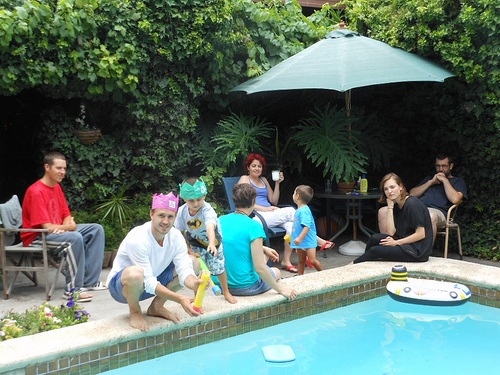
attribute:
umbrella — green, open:
[227, 14, 460, 111]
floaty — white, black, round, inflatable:
[384, 263, 475, 310]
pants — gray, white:
[27, 222, 115, 301]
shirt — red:
[17, 174, 76, 251]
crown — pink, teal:
[149, 186, 180, 213]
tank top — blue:
[245, 173, 274, 211]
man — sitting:
[419, 150, 468, 237]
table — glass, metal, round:
[311, 180, 389, 245]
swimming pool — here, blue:
[7, 250, 499, 369]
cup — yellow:
[357, 176, 372, 195]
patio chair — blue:
[219, 171, 245, 219]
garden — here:
[0, 290, 91, 340]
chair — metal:
[1, 193, 61, 293]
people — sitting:
[8, 145, 469, 264]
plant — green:
[302, 113, 379, 193]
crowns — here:
[147, 176, 213, 211]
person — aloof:
[358, 171, 439, 263]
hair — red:
[241, 157, 271, 164]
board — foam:
[261, 336, 300, 363]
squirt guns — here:
[187, 269, 219, 317]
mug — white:
[270, 168, 283, 183]